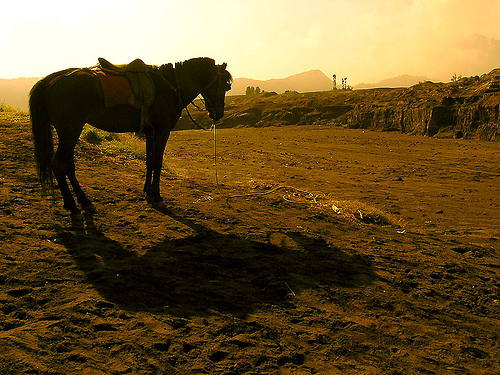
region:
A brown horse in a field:
[19, 44, 269, 226]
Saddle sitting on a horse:
[69, 52, 179, 127]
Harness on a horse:
[160, 52, 255, 196]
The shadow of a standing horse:
[38, 199, 435, 330]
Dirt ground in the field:
[31, 302, 452, 372]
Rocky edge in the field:
[354, 79, 484, 138]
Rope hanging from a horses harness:
[201, 117, 293, 209]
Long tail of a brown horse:
[18, 68, 75, 207]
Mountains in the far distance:
[225, 7, 475, 97]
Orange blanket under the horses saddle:
[69, 52, 161, 124]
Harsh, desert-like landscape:
[5, 38, 492, 356]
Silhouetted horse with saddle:
[10, 45, 236, 215]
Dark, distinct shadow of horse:
[25, 205, 381, 325]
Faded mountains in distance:
[0, 30, 495, 100]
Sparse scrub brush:
[67, 120, 157, 155]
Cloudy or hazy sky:
[0, 0, 497, 70]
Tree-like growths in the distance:
[240, 80, 262, 92]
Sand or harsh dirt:
[0, 125, 480, 370]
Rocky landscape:
[190, 70, 495, 135]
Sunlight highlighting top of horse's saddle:
[83, 52, 163, 130]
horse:
[32, 47, 230, 227]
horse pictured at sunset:
[34, 53, 234, 233]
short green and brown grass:
[25, 261, 172, 353]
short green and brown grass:
[155, 276, 266, 345]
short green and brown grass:
[253, 271, 370, 339]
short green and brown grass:
[365, 268, 441, 345]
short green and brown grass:
[260, 139, 331, 171]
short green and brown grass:
[336, 146, 437, 185]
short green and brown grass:
[422, 159, 472, 246]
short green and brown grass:
[205, 154, 282, 217]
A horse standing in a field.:
[29, 53, 233, 218]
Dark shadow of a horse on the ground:
[53, 208, 375, 322]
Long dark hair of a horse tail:
[25, 83, 59, 200]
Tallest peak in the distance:
[291, 67, 333, 89]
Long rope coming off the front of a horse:
[211, 122, 326, 212]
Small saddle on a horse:
[96, 52, 157, 110]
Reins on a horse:
[158, 61, 214, 131]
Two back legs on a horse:
[50, 124, 97, 226]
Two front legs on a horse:
[139, 125, 166, 209]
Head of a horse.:
[199, 57, 232, 122]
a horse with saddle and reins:
[27, 54, 233, 219]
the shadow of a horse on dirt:
[60, 197, 380, 327]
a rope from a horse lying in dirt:
[211, 123, 309, 198]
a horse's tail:
[28, 74, 54, 199]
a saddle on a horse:
[92, 54, 159, 134]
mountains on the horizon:
[240, 69, 437, 91]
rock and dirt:
[253, 69, 498, 184]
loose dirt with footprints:
[0, 307, 498, 374]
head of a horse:
[180, 56, 231, 123]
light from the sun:
[0, 2, 89, 64]